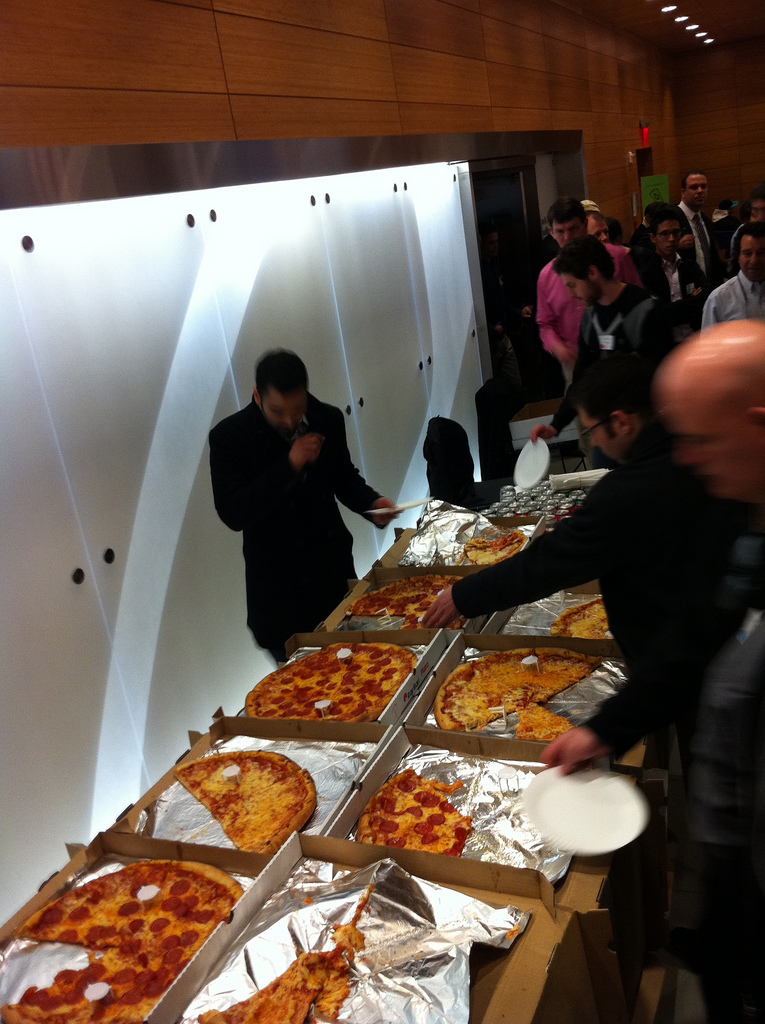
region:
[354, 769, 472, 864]
pepperoni pizza on a buffet line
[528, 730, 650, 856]
right hand holding a white plate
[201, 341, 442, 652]
man with a black suit going through a pizza buffet line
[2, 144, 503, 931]
folding white wall next to buffet table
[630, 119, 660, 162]
red exit sign above a door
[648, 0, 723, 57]
five lights in the ceiling of the banquet hall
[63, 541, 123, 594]
knobs on the folding white wall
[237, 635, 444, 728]
A pepperoni pizza in a box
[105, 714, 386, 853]
Half a cheese pizza in a box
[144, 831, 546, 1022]
A box with one slice of pizza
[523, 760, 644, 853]
A round plate being held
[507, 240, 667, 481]
A person picking up a plate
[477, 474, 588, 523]
A group of cans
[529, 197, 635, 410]
A person in a pink shirt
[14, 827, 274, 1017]
A pizza with one slice missing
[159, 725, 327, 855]
THIS IS ONLY HALF OF A PIZZA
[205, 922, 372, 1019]
ONLY ONE SLICE IS LEFT IN THIS BOX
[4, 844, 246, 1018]
THIS PIZZA IS MISSING ONE SLICE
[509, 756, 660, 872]
THE PLATE IS WHITE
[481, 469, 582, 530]
MANY CANS ARE AT THE END OF THE TABLE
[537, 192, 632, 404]
Man wearing a pink shirt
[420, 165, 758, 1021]
Queue for pizza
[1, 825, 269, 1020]
An open box containing pepperoni pizza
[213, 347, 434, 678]
Man holding a white paper plate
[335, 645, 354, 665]
White plastic piece that prevents pizza cheese from situck to the top of a box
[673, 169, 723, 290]
Man wearing a necktie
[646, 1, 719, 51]
White colored overhead lighting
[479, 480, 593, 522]
Multiple cans of a drink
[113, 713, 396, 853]
Box containing half of a cheese pizza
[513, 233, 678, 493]
Man with a tag around his neck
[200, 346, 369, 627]
a person is standing up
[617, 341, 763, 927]
a person is standing up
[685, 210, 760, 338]
a person is standing up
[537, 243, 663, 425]
a person is standing up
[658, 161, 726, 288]
a person is standing up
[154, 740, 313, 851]
a pizza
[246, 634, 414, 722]
a pizza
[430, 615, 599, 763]
a pizza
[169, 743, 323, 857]
this pizza is half gone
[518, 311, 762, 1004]
the bald man holds a paper plate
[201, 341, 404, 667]
this man seems to be on the phone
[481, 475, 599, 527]
a box of canned beverages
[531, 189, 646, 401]
this man is wearing a pink shirt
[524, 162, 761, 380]
people are waiting in line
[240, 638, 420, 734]
a whole pepperoni pizza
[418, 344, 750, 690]
this man is taking a slice of pizza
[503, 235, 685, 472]
this person is taking a plate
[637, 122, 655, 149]
the exit sign is lighted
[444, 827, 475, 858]
pepperoni on the pizza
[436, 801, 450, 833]
pepperoni on the pizza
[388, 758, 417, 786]
pepperoni on the pizza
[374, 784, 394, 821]
pepperoni on the pizza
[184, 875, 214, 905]
pepperoni on the pizza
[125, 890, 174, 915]
pepperoni on the pizza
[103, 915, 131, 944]
pepperoni on the pizza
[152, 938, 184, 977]
pepperoni on the pizza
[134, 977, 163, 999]
pepperoni on the pizza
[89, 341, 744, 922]
a gathering to eat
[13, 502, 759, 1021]
a table full of pizza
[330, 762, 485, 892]
a pepperoni pizza